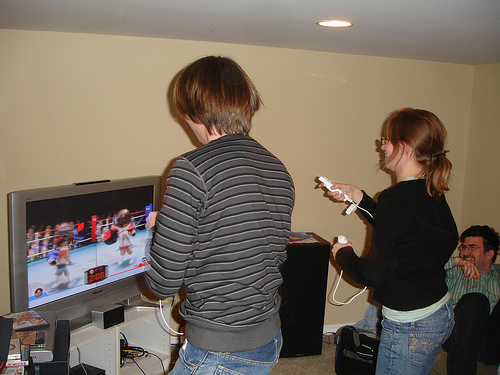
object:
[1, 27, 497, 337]
wall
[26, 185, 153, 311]
boxing game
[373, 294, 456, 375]
jeans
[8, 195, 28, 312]
frame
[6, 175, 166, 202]
frame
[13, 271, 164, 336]
frame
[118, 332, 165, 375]
cords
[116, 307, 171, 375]
shelf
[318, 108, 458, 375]
girl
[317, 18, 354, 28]
light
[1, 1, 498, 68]
ceiling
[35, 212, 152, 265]
video game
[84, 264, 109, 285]
timer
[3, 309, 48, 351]
games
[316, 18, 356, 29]
game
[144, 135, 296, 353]
shirt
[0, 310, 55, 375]
dvds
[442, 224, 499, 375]
man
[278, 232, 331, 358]
speakers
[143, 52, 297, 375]
man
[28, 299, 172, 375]
tv stand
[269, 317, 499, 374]
floor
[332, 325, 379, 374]
bag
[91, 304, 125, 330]
speaker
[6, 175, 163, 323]
tv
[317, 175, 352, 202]
controller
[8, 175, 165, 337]
game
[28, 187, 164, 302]
game